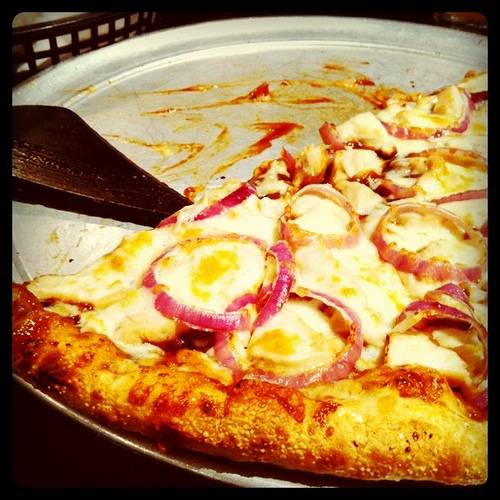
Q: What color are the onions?
A: Purple.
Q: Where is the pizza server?
A: On the platter.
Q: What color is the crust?
A: Brown.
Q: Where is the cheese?
A: On the pizza.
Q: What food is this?
A: Pizza.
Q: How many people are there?
A: 0.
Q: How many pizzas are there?
A: 1.